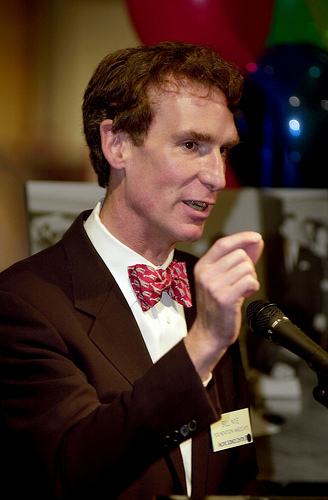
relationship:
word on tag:
[214, 423, 249, 436] [110, 248, 218, 321]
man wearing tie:
[9, 50, 247, 478] [121, 253, 196, 310]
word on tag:
[221, 418, 230, 427] [206, 404, 259, 458]